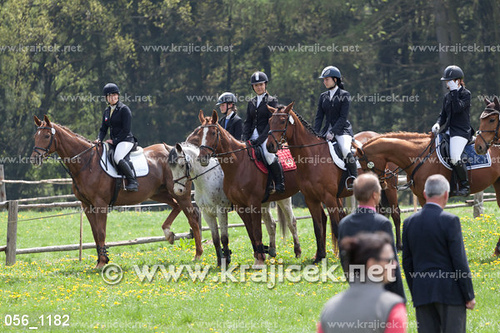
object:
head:
[420, 173, 451, 208]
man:
[333, 169, 405, 307]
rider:
[91, 81, 139, 192]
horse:
[28, 113, 204, 272]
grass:
[0, 208, 499, 332]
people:
[398, 172, 474, 332]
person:
[213, 90, 245, 142]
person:
[236, 69, 282, 197]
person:
[311, 65, 358, 191]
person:
[427, 63, 477, 198]